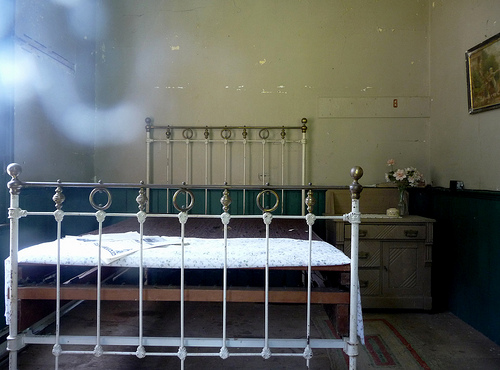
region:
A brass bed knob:
[350, 165, 362, 194]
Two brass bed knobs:
[5, 160, 364, 201]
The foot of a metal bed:
[2, 162, 362, 353]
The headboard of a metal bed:
[143, 114, 315, 220]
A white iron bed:
[7, 117, 364, 369]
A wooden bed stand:
[326, 183, 434, 315]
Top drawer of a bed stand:
[341, 219, 431, 240]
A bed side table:
[327, 185, 440, 312]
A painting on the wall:
[463, 32, 498, 110]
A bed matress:
[10, 214, 352, 266]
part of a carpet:
[425, 343, 445, 358]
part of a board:
[388, 243, 425, 273]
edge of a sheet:
[228, 258, 250, 285]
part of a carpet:
[389, 340, 411, 359]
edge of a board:
[391, 297, 414, 312]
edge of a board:
[421, 240, 444, 270]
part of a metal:
[297, 302, 315, 343]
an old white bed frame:
[3, 99, 379, 366]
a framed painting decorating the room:
[448, 29, 498, 121]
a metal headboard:
[124, 115, 334, 225]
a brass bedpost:
[343, 164, 376, 189]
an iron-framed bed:
[2, 87, 448, 364]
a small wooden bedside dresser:
[331, 176, 444, 331]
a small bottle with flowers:
[388, 155, 430, 221]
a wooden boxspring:
[20, 243, 356, 316]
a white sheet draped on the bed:
[3, 227, 348, 268]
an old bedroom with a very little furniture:
[1, 0, 488, 367]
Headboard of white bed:
[135, 106, 321, 228]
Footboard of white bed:
[4, 162, 384, 369]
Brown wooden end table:
[315, 183, 446, 319]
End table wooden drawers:
[345, 226, 382, 302]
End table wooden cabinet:
[379, 239, 439, 302]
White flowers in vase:
[378, 154, 427, 194]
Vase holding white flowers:
[390, 184, 417, 223]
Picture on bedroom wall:
[451, 36, 498, 122]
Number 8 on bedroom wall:
[380, 92, 408, 112]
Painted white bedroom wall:
[96, 4, 433, 181]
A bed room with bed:
[11, 7, 498, 357]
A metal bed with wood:
[8, 156, 380, 359]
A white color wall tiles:
[333, 45, 410, 112]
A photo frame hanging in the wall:
[461, 43, 498, 111]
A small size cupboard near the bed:
[336, 188, 441, 310]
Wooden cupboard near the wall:
[331, 191, 448, 301]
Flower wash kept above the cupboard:
[386, 153, 426, 218]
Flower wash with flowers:
[387, 153, 429, 215]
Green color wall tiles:
[451, 215, 489, 311]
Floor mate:
[369, 325, 415, 368]